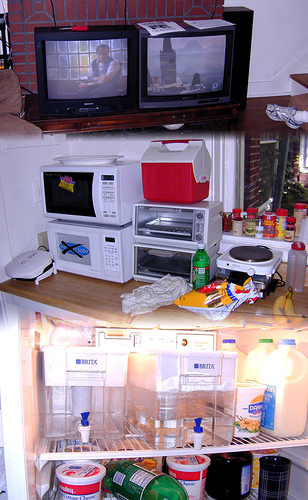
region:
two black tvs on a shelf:
[33, 5, 253, 116]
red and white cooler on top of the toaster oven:
[137, 136, 213, 203]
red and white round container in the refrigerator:
[165, 453, 211, 491]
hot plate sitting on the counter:
[215, 231, 288, 275]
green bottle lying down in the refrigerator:
[100, 459, 183, 498]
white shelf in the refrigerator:
[36, 429, 303, 457]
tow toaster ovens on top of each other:
[127, 200, 219, 285]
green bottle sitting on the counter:
[190, 242, 205, 287]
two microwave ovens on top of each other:
[41, 156, 142, 282]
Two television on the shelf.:
[24, 12, 226, 120]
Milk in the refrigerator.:
[245, 337, 302, 444]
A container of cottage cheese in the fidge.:
[168, 453, 213, 495]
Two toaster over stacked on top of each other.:
[132, 195, 218, 292]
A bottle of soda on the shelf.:
[113, 466, 175, 495]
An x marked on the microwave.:
[51, 229, 89, 262]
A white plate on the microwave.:
[59, 141, 121, 167]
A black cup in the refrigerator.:
[255, 450, 290, 494]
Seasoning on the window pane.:
[229, 199, 307, 242]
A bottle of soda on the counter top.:
[185, 239, 216, 289]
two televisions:
[37, 20, 232, 109]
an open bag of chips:
[177, 277, 256, 320]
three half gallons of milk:
[223, 338, 307, 435]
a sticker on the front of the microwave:
[55, 175, 77, 193]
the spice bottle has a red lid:
[243, 207, 257, 235]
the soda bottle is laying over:
[108, 460, 186, 497]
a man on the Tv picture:
[70, 43, 125, 93]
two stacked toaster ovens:
[131, 200, 219, 283]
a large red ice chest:
[141, 137, 211, 203]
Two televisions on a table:
[32, 23, 236, 108]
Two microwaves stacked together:
[36, 160, 143, 283]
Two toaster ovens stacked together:
[132, 199, 224, 290]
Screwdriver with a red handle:
[57, 24, 89, 31]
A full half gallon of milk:
[259, 338, 306, 437]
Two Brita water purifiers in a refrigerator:
[39, 343, 238, 451]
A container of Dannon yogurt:
[233, 381, 268, 438]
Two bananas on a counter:
[271, 286, 306, 330]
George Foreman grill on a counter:
[4, 246, 57, 286]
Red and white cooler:
[140, 138, 212, 203]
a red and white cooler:
[140, 137, 212, 202]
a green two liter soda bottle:
[104, 461, 187, 499]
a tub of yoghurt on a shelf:
[234, 383, 267, 437]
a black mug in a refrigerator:
[256, 455, 291, 498]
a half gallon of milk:
[261, 338, 305, 436]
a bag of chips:
[174, 276, 259, 320]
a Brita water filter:
[42, 350, 129, 443]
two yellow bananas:
[273, 286, 307, 326]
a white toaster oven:
[132, 199, 223, 248]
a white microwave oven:
[39, 160, 143, 226]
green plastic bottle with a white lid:
[190, 242, 209, 288]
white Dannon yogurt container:
[232, 382, 265, 437]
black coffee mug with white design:
[257, 455, 290, 498]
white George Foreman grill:
[4, 249, 57, 285]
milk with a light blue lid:
[261, 338, 306, 436]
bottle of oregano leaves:
[243, 206, 256, 236]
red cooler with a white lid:
[140, 138, 212, 202]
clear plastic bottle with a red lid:
[284, 241, 306, 293]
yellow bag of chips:
[172, 275, 262, 318]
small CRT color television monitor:
[33, 25, 136, 113]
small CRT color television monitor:
[138, 18, 234, 106]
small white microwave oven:
[40, 157, 142, 228]